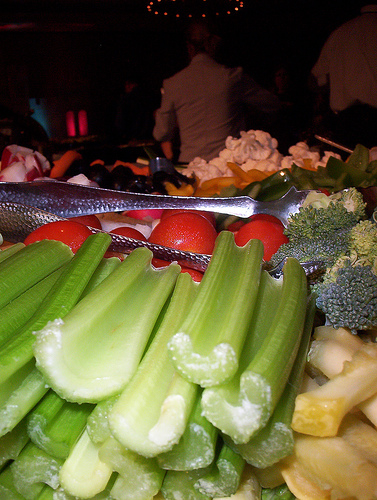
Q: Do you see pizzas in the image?
A: No, there are no pizzas.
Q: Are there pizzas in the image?
A: No, there are no pizzas.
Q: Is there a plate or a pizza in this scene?
A: No, there are no pizzas or plates.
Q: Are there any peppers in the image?
A: Yes, there are peppers.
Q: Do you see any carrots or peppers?
A: Yes, there are peppers.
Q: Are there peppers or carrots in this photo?
A: Yes, there are peppers.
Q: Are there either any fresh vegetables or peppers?
A: Yes, there are fresh peppers.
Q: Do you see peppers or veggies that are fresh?
A: Yes, the peppers are fresh.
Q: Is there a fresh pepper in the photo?
A: Yes, there are fresh peppers.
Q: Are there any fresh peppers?
A: Yes, there are fresh peppers.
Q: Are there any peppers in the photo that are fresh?
A: Yes, there are fresh peppers.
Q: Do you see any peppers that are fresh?
A: Yes, there are peppers that are fresh.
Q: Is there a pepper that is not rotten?
A: Yes, there are fresh peppers.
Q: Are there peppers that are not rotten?
A: Yes, there are fresh peppers.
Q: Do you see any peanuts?
A: No, there are no peanuts.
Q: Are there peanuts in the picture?
A: No, there are no peanuts.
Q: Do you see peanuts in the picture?
A: No, there are no peanuts.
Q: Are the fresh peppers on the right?
A: Yes, the peppers are on the right of the image.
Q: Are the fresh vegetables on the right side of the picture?
A: Yes, the peppers are on the right of the image.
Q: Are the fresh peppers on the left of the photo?
A: No, the peppers are on the right of the image.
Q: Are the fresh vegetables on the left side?
A: No, the peppers are on the right of the image.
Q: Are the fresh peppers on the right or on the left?
A: The peppers are on the right of the image.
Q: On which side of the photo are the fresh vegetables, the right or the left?
A: The peppers are on the right of the image.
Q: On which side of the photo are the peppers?
A: The peppers are on the right of the image.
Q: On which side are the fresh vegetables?
A: The peppers are on the right of the image.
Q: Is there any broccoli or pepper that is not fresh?
A: No, there are peppers but they are fresh.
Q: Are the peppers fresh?
A: Yes, the peppers are fresh.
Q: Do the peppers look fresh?
A: Yes, the peppers are fresh.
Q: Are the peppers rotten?
A: No, the peppers are fresh.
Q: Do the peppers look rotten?
A: No, the peppers are fresh.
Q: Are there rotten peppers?
A: No, there are peppers but they are fresh.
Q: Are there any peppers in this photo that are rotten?
A: No, there are peppers but they are fresh.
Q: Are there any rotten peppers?
A: No, there are peppers but they are fresh.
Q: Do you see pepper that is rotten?
A: No, there are peppers but they are fresh.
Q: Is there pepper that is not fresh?
A: No, there are peppers but they are fresh.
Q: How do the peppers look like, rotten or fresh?
A: The peppers are fresh.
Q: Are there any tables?
A: Yes, there is a table.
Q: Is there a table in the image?
A: Yes, there is a table.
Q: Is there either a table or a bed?
A: Yes, there is a table.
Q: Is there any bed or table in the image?
A: Yes, there is a table.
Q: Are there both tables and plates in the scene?
A: No, there is a table but no plates.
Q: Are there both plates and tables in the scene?
A: No, there is a table but no plates.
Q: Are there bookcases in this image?
A: No, there are no bookcases.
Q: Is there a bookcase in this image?
A: No, there are no bookcases.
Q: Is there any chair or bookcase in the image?
A: No, there are no bookcases or chairs.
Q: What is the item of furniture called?
A: The piece of furniture is a table.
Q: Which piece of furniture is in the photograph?
A: The piece of furniture is a table.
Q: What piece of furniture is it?
A: The piece of furniture is a table.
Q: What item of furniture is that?
A: This is a table.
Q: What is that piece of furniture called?
A: This is a table.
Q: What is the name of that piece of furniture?
A: This is a table.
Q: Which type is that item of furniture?
A: This is a table.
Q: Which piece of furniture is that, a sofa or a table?
A: This is a table.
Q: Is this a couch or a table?
A: This is a table.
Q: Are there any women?
A: Yes, there is a woman.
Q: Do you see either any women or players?
A: Yes, there is a woman.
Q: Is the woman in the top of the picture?
A: Yes, the woman is in the top of the image.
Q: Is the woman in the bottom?
A: No, the woman is in the top of the image.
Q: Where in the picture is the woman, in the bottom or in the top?
A: The woman is in the top of the image.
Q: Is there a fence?
A: No, there are no fences.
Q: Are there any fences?
A: No, there are no fences.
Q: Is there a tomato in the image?
A: Yes, there is a tomato.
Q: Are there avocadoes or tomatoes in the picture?
A: Yes, there is a tomato.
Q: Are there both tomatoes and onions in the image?
A: No, there is a tomato but no onions.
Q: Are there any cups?
A: No, there are no cups.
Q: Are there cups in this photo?
A: No, there are no cups.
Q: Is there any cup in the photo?
A: No, there are no cups.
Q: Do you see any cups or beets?
A: No, there are no cups or beets.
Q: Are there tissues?
A: No, there are no tissues.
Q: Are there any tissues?
A: No, there are no tissues.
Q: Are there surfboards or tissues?
A: No, there are no tissues or surfboards.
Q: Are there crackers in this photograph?
A: No, there are no crackers.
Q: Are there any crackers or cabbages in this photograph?
A: No, there are no crackers or cabbages.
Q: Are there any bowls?
A: No, there are no bowls.